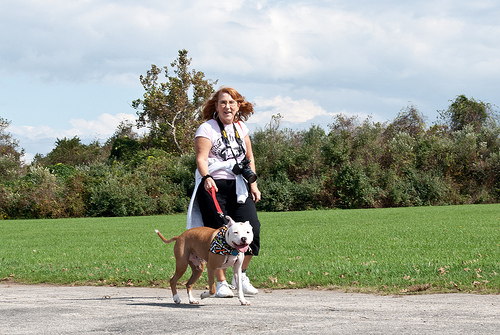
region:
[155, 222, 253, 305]
A white and brown pittbull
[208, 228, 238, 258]
A bandanna around the dog's neck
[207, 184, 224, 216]
A short pink leash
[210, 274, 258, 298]
A pair of white tennis shoes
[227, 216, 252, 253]
A dog's white face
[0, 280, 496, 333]
A paved pathway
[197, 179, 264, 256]
A pair of black shorts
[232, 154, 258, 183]
A black camera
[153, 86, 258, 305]
A woman walking a pitt bull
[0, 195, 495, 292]
A field of green grass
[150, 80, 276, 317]
A woman walking her dog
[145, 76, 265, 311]
A woman walking her dog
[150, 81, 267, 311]
A woman walking her dog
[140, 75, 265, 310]
A woman walking her dog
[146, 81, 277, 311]
A woman walking her dog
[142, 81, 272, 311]
A woman walking her dog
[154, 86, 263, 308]
woman walking the dog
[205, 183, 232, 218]
leash holding the dog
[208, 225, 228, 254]
hankerchief around dog next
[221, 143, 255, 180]
camera around woman's neck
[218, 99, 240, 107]
glasses on the woman's face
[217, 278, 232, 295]
shoe on the woman's foot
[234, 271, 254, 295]
shoe on the woman's foot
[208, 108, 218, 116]
earrings on woman ear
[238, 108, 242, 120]
earring on woman's ear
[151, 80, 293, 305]
woman walking a dog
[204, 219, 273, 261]
dog with handkerchief around neck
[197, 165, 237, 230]
woman holding red leash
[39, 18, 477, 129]
sky covered with large white clouds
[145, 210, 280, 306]
brown and white dog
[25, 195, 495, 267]
large grassy green field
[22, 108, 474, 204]
green trees along back of field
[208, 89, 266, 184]
woman with camera around her beck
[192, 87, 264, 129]
woman with red hair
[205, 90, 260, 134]
woman wearing eye glasses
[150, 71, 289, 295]
a woman with the dog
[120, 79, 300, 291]
a woman with the dog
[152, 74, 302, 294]
a woman with the dog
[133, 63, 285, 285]
a woman with the dog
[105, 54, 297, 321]
a woman with the dog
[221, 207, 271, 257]
dog's face is white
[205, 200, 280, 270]
dog's face is white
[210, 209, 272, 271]
dog's face is white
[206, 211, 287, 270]
dog's face is white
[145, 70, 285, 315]
A woman walking her dog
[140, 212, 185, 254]
The tail of a dog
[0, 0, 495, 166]
The sky is very cloudy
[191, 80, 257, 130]
Woman has brown hair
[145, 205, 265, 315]
A brown and white dog